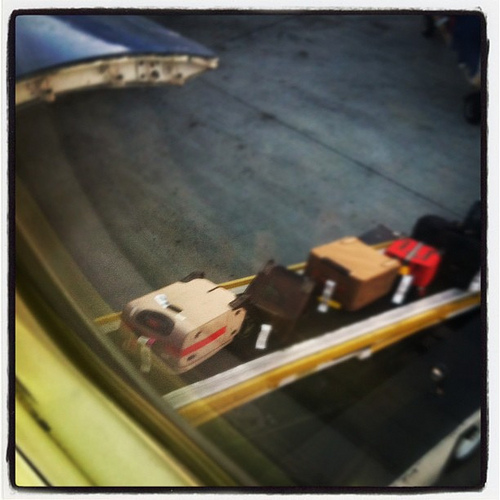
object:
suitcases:
[411, 214, 484, 292]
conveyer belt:
[94, 233, 483, 426]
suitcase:
[119, 270, 252, 374]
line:
[165, 327, 228, 358]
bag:
[384, 237, 447, 287]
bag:
[224, 258, 316, 363]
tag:
[132, 334, 150, 367]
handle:
[140, 344, 152, 373]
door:
[15, 13, 221, 107]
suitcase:
[305, 236, 403, 313]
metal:
[16, 291, 200, 488]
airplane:
[15, 14, 482, 485]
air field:
[9, 11, 484, 488]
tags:
[316, 279, 337, 313]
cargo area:
[13, 14, 482, 489]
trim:
[194, 331, 201, 340]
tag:
[255, 324, 272, 350]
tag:
[391, 275, 413, 304]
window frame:
[9, 10, 487, 494]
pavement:
[13, 18, 482, 483]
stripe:
[179, 310, 231, 349]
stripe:
[169, 299, 475, 427]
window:
[16, 14, 485, 487]